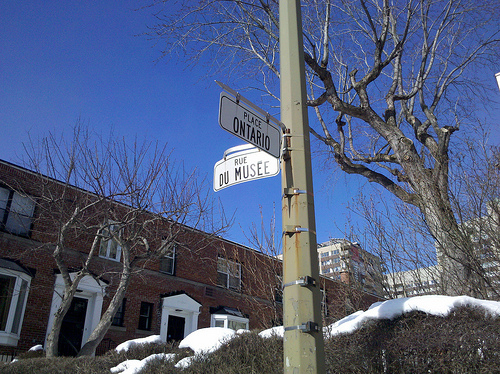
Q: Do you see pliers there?
A: No, there are no pliers.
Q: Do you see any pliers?
A: No, there are no pliers.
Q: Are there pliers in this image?
A: No, there are no pliers.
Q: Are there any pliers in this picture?
A: No, there are no pliers.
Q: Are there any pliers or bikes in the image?
A: No, there are no pliers or bikes.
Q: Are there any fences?
A: No, there are no fences.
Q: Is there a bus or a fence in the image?
A: No, there are no fences or buses.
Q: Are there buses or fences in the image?
A: No, there are no fences or buses.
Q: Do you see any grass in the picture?
A: Yes, there is grass.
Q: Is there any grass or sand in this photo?
A: Yes, there is grass.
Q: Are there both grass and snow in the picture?
A: Yes, there are both grass and snow.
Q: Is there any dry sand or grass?
A: Yes, there is dry grass.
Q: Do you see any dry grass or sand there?
A: Yes, there is dry grass.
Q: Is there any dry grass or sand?
A: Yes, there is dry grass.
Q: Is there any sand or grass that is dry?
A: Yes, the grass is dry.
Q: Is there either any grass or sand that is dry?
A: Yes, the grass is dry.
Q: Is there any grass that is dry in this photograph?
A: Yes, there is dry grass.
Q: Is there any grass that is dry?
A: Yes, there is grass that is dry.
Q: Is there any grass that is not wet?
A: Yes, there is dry grass.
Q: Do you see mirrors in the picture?
A: No, there are no mirrors.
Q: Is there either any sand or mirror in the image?
A: No, there are no mirrors or sand.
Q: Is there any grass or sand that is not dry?
A: No, there is grass but it is dry.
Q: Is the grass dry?
A: Yes, the grass is dry.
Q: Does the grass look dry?
A: Yes, the grass is dry.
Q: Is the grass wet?
A: No, the grass is dry.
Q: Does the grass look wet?
A: No, the grass is dry.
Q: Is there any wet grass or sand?
A: No, there is grass but it is dry.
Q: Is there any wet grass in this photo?
A: No, there is grass but it is dry.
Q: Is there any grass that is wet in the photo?
A: No, there is grass but it is dry.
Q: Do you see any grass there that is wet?
A: No, there is grass but it is dry.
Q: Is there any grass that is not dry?
A: No, there is grass but it is dry.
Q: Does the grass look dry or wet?
A: The grass is dry.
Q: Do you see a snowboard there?
A: No, there are no snowboards.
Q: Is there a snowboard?
A: No, there are no snowboards.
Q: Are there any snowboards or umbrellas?
A: No, there are no snowboards or umbrellas.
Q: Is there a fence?
A: No, there are no fences.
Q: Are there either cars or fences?
A: No, there are no fences or cars.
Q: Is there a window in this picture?
A: Yes, there is a window.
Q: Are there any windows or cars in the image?
A: Yes, there is a window.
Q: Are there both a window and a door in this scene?
A: Yes, there are both a window and a door.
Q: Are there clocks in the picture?
A: No, there are no clocks.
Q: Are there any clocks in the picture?
A: No, there are no clocks.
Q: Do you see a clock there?
A: No, there are no clocks.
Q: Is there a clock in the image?
A: No, there are no clocks.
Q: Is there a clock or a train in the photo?
A: No, there are no clocks or trains.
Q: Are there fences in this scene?
A: No, there are no fences.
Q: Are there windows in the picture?
A: Yes, there is a window.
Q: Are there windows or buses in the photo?
A: Yes, there is a window.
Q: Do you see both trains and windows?
A: No, there is a window but no trains.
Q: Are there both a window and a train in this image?
A: No, there is a window but no trains.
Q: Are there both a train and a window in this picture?
A: No, there is a window but no trains.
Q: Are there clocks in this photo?
A: No, there are no clocks.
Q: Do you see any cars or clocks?
A: No, there are no clocks or cars.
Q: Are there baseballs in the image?
A: No, there are no baseballs.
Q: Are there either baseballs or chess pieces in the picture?
A: No, there are no baseballs or chess pieces.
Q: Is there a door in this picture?
A: Yes, there is a door.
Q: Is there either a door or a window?
A: Yes, there is a door.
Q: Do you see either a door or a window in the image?
A: Yes, there is a door.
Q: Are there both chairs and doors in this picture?
A: No, there is a door but no chairs.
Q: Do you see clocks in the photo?
A: No, there are no clocks.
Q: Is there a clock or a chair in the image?
A: No, there are no clocks or chairs.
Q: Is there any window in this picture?
A: Yes, there is a window.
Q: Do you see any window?
A: Yes, there is a window.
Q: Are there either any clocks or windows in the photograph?
A: Yes, there is a window.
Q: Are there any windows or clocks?
A: Yes, there is a window.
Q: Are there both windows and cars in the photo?
A: No, there is a window but no cars.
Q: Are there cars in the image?
A: No, there are no cars.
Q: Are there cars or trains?
A: No, there are no cars or trains.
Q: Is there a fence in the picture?
A: No, there are no fences.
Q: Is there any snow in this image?
A: Yes, there is snow.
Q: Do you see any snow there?
A: Yes, there is snow.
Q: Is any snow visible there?
A: Yes, there is snow.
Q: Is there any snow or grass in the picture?
A: Yes, there is snow.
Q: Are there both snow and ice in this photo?
A: No, there is snow but no ice.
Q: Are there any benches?
A: No, there are no benches.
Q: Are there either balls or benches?
A: No, there are no benches or balls.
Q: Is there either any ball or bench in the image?
A: No, there are no benches or balls.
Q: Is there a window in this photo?
A: Yes, there is a window.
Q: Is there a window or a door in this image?
A: Yes, there is a window.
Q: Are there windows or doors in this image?
A: Yes, there is a window.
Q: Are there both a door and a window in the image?
A: Yes, there are both a window and a door.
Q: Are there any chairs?
A: No, there are no chairs.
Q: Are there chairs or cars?
A: No, there are no chairs or cars.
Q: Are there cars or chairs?
A: No, there are no chairs or cars.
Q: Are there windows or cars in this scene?
A: Yes, there is a window.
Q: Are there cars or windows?
A: Yes, there is a window.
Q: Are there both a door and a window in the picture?
A: Yes, there are both a window and a door.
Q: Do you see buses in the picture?
A: No, there are no buses.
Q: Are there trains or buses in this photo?
A: No, there are no buses or trains.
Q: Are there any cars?
A: No, there are no cars.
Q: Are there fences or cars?
A: No, there are no cars or fences.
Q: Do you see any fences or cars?
A: No, there are no cars or fences.